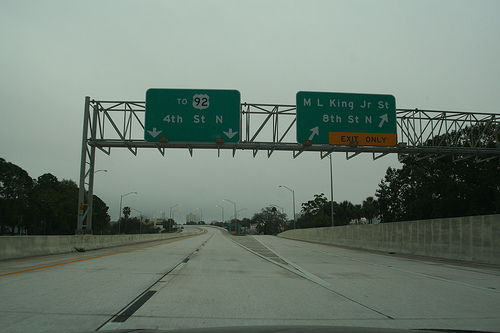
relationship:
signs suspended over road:
[143, 87, 398, 149] [9, 227, 484, 328]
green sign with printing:
[297, 90, 396, 145] [167, 96, 393, 144]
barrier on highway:
[290, 203, 495, 280] [175, 210, 363, 331]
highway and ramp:
[188, 240, 246, 296] [192, 218, 220, 235]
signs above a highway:
[143, 87, 398, 149] [1, 222, 498, 329]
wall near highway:
[265, 220, 483, 264] [89, 162, 495, 315]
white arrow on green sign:
[378, 112, 391, 127] [295, 88, 400, 155]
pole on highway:
[271, 182, 302, 221] [0, 186, 497, 331]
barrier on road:
[11, 234, 89, 259] [48, 230, 91, 259]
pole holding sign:
[75, 96, 89, 230] [144, 87, 241, 149]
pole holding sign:
[87, 104, 99, 231] [295, 90, 397, 151]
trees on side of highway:
[371, 115, 498, 220] [1, 222, 498, 329]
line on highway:
[55, 236, 200, 258] [91, 221, 435, 328]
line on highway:
[107, 284, 160, 329] [2, 222, 497, 333]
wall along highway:
[277, 214, 500, 266] [2, 222, 497, 333]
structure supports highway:
[77, 83, 497, 238] [2, 222, 497, 333]